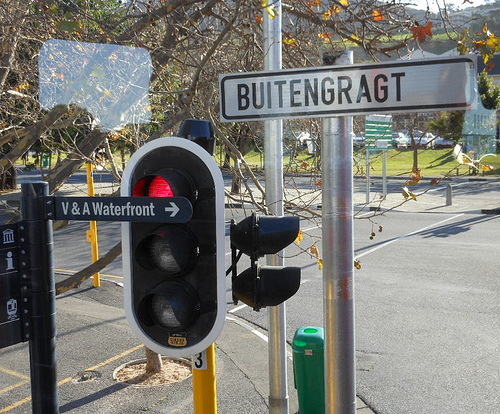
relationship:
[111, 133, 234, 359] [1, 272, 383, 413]
stop light on street corner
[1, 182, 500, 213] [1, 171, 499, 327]
barricade on road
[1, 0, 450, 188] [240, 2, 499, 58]
trees have leaves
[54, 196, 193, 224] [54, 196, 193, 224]
street sign with street sign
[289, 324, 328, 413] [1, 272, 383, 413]
trash can on street corner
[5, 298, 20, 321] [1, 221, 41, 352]
train on sign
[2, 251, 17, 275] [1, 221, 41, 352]
icon on sign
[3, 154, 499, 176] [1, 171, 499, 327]
grass near road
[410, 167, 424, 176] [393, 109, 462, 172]
mulch around tree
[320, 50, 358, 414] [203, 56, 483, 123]
pole holds sign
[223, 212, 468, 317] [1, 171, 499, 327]
line on road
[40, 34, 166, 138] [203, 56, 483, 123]
reflection of sign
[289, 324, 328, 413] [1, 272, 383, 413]
box on sidewalk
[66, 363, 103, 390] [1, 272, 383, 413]
indent in pavement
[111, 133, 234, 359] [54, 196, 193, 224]
stop light behind street sign